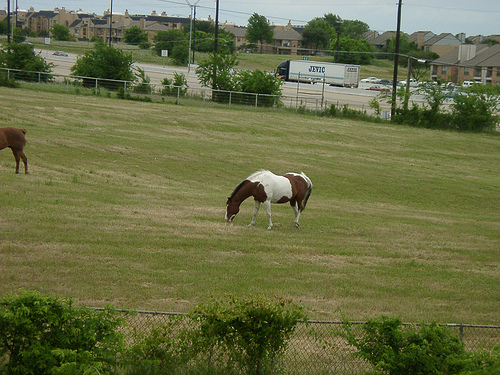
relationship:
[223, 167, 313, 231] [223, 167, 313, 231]
horse has horse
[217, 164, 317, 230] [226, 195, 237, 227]
horse has face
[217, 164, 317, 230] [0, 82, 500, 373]
horse bending grass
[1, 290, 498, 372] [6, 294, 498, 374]
plants growing fence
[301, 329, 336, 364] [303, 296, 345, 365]
fence around field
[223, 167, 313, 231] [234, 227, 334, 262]
horse grazing field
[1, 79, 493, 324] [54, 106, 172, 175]
field grazing grass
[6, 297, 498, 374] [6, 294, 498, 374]
plant life growing fence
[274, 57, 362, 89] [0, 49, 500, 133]
truck going road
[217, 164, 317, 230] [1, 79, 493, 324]
horse standing field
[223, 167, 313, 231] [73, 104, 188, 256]
horse standing field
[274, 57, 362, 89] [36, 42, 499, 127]
truck driving road